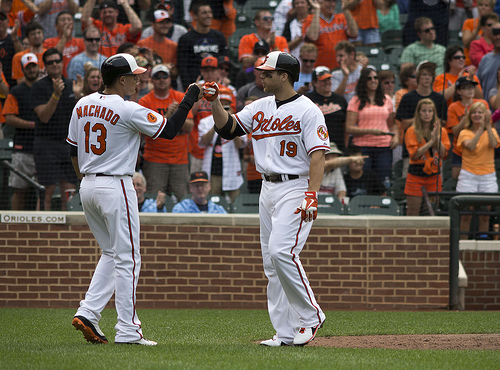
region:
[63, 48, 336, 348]
two baseball players on a field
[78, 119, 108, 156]
number print on a jersey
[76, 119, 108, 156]
number 13 print on a shirt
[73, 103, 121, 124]
name print on a jersey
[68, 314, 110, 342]
baseball cleat on baseball player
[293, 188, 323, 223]
red and white glove on a baseball player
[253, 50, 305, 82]
hat on a baseball player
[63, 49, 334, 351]
two baseball players knuckle touching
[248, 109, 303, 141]
large print on a baseball jersey reading Orioles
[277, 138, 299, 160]
number 19 print on a jersey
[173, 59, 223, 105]
two players touching head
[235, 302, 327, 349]
player wearing white cleats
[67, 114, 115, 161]
number 13 on a players jersey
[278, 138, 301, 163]
number 19 on a players jersey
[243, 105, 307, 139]
Orioles written on the jersey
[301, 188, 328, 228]
man wearing a baseball glove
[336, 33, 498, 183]
people watching a baseball game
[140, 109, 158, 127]
logo on a jerset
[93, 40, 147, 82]
playing wearing a helmet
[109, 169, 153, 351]
orange strip on pants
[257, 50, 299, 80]
cap on player's head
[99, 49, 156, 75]
cap on player's head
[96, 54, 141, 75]
hat on player's head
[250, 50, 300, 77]
hat on player's head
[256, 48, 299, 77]
cap on man's head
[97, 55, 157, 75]
cap on man's head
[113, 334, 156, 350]
shoe on player's foot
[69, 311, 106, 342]
shoe on player's foot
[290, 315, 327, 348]
shoe on player's foot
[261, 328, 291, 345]
shoe on player's foot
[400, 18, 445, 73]
Man wearing a green shirt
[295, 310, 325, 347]
White and orange cleat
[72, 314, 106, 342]
Black and orange cleat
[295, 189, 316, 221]
orange and white glove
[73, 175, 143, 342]
White pants being worn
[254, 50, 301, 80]
A baseball helmet on a head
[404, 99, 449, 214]
Woman wearing an orange shirt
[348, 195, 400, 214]
The top of a chair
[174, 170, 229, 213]
Man wearing a blue shirt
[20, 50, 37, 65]
White and orange baseball cap being worn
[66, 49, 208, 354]
baseball player is wearing a white jersey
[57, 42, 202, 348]
baseball player is wearing a batting helmet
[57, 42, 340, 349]
baseball players are bumping fists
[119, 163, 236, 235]
two men sitting in audience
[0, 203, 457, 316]
brick wall separating field from audience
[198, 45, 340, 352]
baseball player is wearing orange gloves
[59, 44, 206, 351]
baseball player is wearing black sleeves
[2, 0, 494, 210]
audience is applauding players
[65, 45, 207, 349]
baseball player is wearing white pants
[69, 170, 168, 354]
white pants have a red stripe